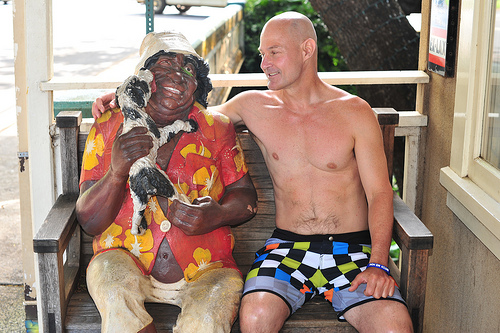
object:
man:
[201, 10, 411, 333]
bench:
[32, 106, 432, 332]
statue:
[73, 30, 258, 332]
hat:
[136, 28, 202, 71]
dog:
[117, 66, 201, 236]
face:
[149, 53, 199, 110]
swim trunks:
[244, 224, 407, 319]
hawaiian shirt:
[74, 100, 248, 280]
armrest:
[32, 191, 77, 252]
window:
[441, 3, 500, 257]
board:
[427, 0, 461, 78]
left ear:
[300, 37, 316, 62]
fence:
[191, 12, 248, 71]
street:
[61, 1, 129, 89]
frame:
[446, 0, 472, 176]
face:
[257, 30, 297, 91]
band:
[366, 263, 391, 276]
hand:
[348, 266, 396, 300]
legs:
[237, 276, 305, 332]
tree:
[308, 0, 419, 108]